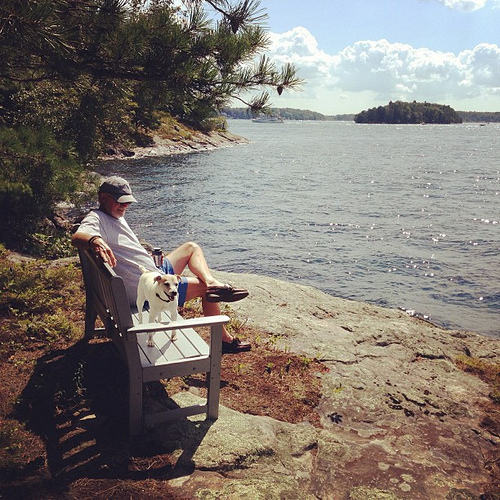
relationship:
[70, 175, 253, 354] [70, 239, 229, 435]
man sitting on bench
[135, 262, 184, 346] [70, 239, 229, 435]
dog standing on bench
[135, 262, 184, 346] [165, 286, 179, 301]
dog has muzzle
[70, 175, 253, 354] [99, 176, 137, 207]
man wearing cap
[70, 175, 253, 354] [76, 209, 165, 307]
man wearing t shirt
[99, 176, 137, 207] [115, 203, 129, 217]
cap covering face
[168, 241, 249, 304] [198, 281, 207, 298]
leg over knee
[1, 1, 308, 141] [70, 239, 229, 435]
branch hanging over bench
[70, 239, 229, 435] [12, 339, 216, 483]
bench casts shadow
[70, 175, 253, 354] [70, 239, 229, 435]
man on top of bench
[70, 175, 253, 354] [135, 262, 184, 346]
man looking at dog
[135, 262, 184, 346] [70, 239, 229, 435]
dog on top of bench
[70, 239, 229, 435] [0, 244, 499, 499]
bench on top of ground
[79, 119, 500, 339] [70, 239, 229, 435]
water near bench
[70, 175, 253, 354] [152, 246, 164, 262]
man holding drink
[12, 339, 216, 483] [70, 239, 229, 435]
shadow behind bench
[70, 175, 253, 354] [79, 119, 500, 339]
man near water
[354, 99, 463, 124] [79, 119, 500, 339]
island floating in water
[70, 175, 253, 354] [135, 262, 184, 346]
man next to dog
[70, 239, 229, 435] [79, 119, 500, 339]
bench overlooks water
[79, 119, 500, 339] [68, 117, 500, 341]
water inside lake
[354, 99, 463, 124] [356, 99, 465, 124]
island covered with trees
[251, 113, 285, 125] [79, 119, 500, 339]
boat floating in water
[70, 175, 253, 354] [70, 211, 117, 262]
man resting arm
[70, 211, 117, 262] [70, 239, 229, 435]
arm on top of bench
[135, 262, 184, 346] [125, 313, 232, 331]
dog facing arm rest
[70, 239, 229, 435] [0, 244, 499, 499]
bench on ground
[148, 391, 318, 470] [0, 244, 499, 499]
rock on ground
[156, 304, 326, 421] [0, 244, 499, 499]
soil on ground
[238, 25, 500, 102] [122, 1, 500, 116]
cloud in sky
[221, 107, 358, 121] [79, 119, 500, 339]
hill across water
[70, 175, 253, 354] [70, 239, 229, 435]
man resting on bench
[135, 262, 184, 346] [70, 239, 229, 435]
dog resting on bench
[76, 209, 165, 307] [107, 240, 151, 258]
t shirt has wrinkle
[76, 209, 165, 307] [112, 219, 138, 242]
t shirt has wrinkle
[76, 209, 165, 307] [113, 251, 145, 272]
t shirt has wrinkle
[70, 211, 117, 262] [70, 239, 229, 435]
arm extended over bench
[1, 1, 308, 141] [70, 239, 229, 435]
branch overlooks bench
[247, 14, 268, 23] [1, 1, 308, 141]
pine needles on branch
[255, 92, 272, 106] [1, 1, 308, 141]
pine needles on branch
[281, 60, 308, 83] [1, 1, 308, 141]
pine needles on branch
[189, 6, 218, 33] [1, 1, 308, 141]
pine needles on branch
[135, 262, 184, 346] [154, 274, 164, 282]
dog has ear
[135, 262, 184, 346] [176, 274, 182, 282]
dog has ear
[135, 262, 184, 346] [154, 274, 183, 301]
dog has face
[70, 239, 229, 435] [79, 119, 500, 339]
bench near water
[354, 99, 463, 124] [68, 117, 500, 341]
island in middle of lake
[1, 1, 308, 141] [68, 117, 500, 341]
branch overhanging lake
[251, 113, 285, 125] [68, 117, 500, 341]
boat in lake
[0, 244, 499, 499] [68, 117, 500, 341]
ground extends into lake